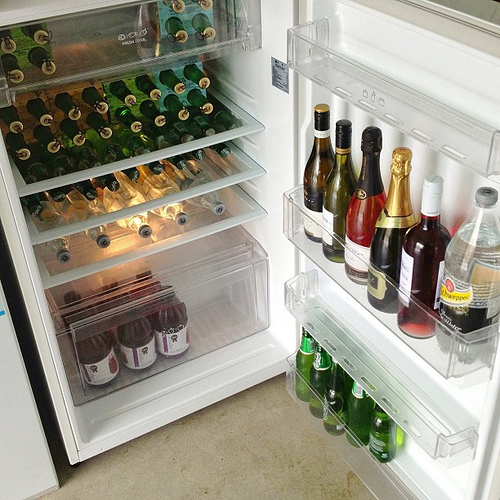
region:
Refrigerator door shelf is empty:
[290, 0, 499, 135]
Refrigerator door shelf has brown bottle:
[286, 82, 328, 269]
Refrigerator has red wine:
[339, 123, 379, 305]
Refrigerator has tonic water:
[429, 175, 496, 376]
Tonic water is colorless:
[433, 183, 498, 374]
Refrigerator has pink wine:
[398, 162, 455, 355]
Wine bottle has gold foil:
[373, 134, 415, 325]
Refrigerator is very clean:
[21, 170, 309, 420]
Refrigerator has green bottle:
[308, 324, 330, 425]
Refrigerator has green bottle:
[341, 365, 376, 465]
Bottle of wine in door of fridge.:
[302, 125, 317, 283]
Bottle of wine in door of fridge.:
[311, 191, 351, 256]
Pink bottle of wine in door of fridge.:
[347, 192, 367, 342]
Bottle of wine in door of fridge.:
[368, 212, 398, 323]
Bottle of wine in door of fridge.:
[395, 252, 422, 342]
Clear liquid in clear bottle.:
[453, 225, 493, 335]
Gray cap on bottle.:
[472, 182, 496, 223]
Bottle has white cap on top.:
[412, 172, 454, 265]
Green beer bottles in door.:
[300, 381, 397, 489]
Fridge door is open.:
[133, 205, 405, 447]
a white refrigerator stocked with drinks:
[6, 7, 489, 484]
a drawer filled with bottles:
[34, 284, 286, 395]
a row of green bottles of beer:
[294, 309, 419, 471]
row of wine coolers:
[2, 20, 263, 160]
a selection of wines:
[301, 71, 443, 347]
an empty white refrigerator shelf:
[305, 8, 498, 110]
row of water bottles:
[42, 183, 259, 271]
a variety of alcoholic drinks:
[1, 47, 448, 457]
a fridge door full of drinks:
[285, 76, 499, 455]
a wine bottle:
[362, 147, 420, 314]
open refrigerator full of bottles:
[49, 7, 469, 459]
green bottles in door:
[289, 333, 399, 464]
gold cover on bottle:
[376, 141, 427, 224]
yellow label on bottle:
[435, 279, 479, 306]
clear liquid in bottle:
[441, 215, 491, 281]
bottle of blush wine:
[385, 174, 452, 340]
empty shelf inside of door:
[298, 19, 476, 136]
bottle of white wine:
[316, 110, 366, 252]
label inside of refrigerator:
[265, 46, 295, 101]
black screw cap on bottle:
[332, 113, 357, 145]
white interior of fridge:
[283, 11, 498, 447]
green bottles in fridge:
[293, 333, 403, 476]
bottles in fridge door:
[290, 89, 482, 326]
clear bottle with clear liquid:
[399, 213, 498, 320]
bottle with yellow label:
[410, 181, 498, 338]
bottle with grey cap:
[434, 181, 497, 388]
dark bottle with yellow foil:
[355, 140, 410, 315]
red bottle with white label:
[380, 175, 446, 338]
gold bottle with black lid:
[282, 108, 333, 242]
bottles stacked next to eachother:
[21, 31, 72, 88]